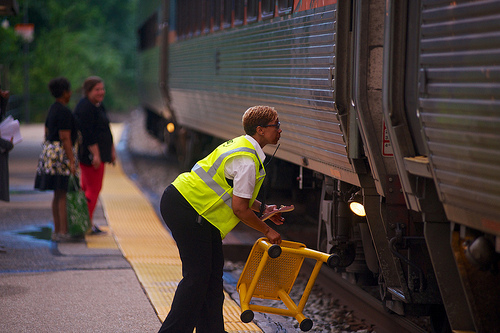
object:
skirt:
[35, 139, 78, 191]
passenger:
[74, 75, 117, 232]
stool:
[234, 237, 344, 330]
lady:
[72, 75, 114, 235]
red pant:
[80, 165, 107, 224]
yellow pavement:
[105, 198, 167, 271]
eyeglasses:
[261, 121, 280, 128]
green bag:
[67, 180, 88, 237]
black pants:
[153, 183, 233, 329]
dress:
[34, 138, 81, 193]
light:
[349, 201, 366, 216]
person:
[159, 104, 284, 331]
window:
[231, 4, 244, 26]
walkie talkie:
[256, 143, 283, 189]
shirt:
[44, 101, 79, 144]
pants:
[79, 161, 105, 223]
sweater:
[73, 95, 114, 167]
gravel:
[323, 305, 372, 330]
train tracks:
[291, 178, 421, 319]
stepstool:
[236, 235, 344, 332]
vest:
[180, 147, 265, 205]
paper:
[0, 116, 23, 145]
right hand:
[69, 163, 76, 175]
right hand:
[91, 152, 101, 169]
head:
[241, 105, 282, 145]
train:
[173, 1, 496, 169]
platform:
[0, 139, 262, 331]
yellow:
[240, 244, 337, 325]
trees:
[1, 2, 101, 74]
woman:
[68, 67, 116, 236]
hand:
[264, 229, 283, 245]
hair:
[242, 104, 279, 136]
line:
[105, 171, 169, 328]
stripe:
[104, 157, 192, 301]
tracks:
[320, 258, 469, 323]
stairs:
[343, 100, 424, 220]